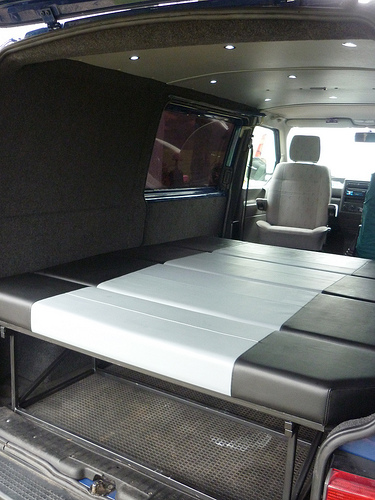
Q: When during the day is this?
A: Day Time.